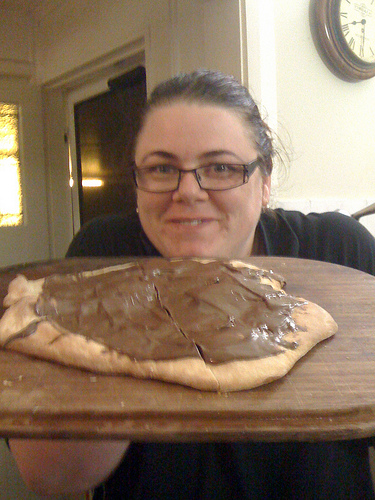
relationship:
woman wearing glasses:
[2, 70, 372, 498] [129, 154, 265, 191]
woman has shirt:
[2, 70, 372, 498] [63, 206, 374, 498]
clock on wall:
[308, 0, 374, 81] [246, 0, 373, 152]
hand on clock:
[345, 17, 366, 27] [306, 0, 373, 87]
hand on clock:
[360, 14, 367, 54] [306, 0, 373, 87]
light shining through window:
[0, 157, 17, 214] [0, 100, 29, 230]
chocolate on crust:
[40, 257, 299, 361] [0, 254, 337, 392]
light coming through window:
[68, 177, 104, 188] [66, 98, 136, 190]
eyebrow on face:
[193, 148, 246, 160] [128, 97, 271, 258]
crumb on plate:
[87, 374, 100, 384] [2, 252, 364, 432]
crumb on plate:
[81, 373, 100, 384] [1, 245, 362, 462]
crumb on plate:
[79, 377, 130, 411] [1, 245, 362, 462]